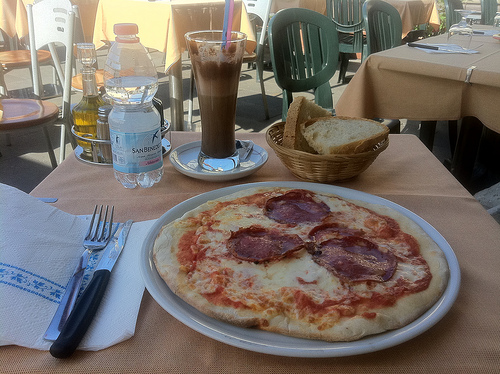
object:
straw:
[222, 3, 239, 48]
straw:
[222, 1, 229, 55]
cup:
[189, 29, 244, 171]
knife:
[46, 221, 132, 359]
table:
[374, 29, 497, 114]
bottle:
[104, 18, 166, 191]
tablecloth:
[1, 124, 496, 372]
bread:
[304, 111, 389, 151]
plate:
[134, 176, 465, 362]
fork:
[38, 199, 129, 358]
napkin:
[0, 181, 158, 351]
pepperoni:
[259, 189, 334, 224]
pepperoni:
[307, 227, 403, 284]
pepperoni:
[223, 223, 305, 265]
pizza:
[149, 183, 455, 346]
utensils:
[36, 198, 135, 356]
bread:
[284, 95, 334, 149]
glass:
[182, 23, 245, 162]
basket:
[265, 109, 388, 183]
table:
[0, 107, 485, 371]